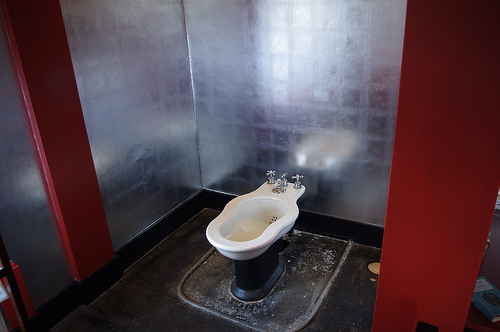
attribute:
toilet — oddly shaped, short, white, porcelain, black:
[206, 169, 308, 302]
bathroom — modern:
[3, 1, 500, 331]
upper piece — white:
[205, 169, 305, 261]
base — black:
[229, 237, 294, 302]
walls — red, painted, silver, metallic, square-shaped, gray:
[1, 2, 499, 329]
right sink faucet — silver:
[290, 174, 308, 190]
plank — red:
[3, 1, 117, 284]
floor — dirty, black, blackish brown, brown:
[46, 206, 380, 331]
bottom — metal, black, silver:
[177, 231, 353, 331]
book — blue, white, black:
[471, 276, 499, 322]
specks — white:
[187, 229, 340, 318]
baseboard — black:
[22, 187, 386, 331]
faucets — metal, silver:
[265, 168, 304, 190]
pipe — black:
[1, 242, 37, 331]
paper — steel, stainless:
[2, 0, 406, 311]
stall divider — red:
[370, 0, 499, 331]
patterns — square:
[2, 1, 406, 310]